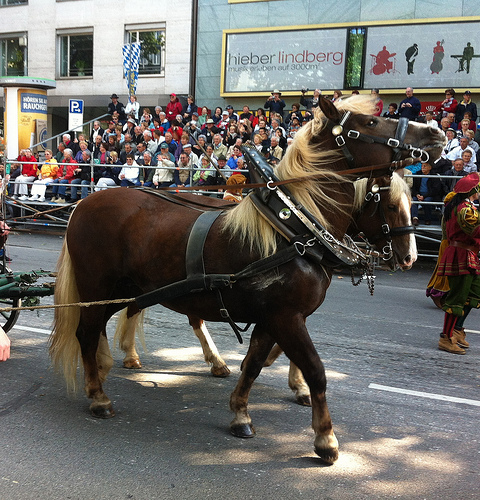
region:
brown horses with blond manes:
[44, 80, 452, 483]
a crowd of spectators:
[13, 64, 314, 178]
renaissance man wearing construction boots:
[432, 168, 477, 362]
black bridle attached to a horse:
[40, 83, 433, 318]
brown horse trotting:
[35, 62, 444, 470]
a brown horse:
[41, 81, 449, 463]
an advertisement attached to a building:
[211, 17, 475, 97]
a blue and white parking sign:
[51, 83, 86, 133]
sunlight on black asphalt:
[344, 395, 475, 491]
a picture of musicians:
[363, 33, 476, 79]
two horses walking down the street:
[44, 97, 423, 473]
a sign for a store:
[212, 18, 478, 101]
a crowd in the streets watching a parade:
[7, 89, 474, 216]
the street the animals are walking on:
[7, 231, 476, 499]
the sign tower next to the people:
[2, 74, 56, 156]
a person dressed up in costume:
[430, 174, 478, 348]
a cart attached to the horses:
[1, 217, 57, 340]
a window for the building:
[60, 26, 94, 80]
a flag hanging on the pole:
[123, 45, 141, 80]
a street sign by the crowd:
[70, 98, 81, 127]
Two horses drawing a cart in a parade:
[12, 59, 450, 485]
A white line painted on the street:
[365, 364, 474, 423]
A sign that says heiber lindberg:
[225, 35, 360, 91]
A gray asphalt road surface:
[30, 417, 230, 482]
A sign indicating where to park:
[61, 79, 97, 136]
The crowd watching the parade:
[107, 91, 253, 186]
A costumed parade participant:
[424, 145, 478, 359]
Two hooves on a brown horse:
[214, 408, 379, 482]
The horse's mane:
[206, 84, 383, 258]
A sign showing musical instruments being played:
[369, 20, 478, 94]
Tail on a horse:
[44, 211, 100, 386]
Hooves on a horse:
[230, 368, 369, 477]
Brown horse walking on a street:
[60, 180, 368, 471]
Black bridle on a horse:
[205, 138, 359, 268]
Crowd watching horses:
[115, 95, 272, 239]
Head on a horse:
[306, 102, 455, 184]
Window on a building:
[215, 16, 433, 105]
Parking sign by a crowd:
[60, 94, 98, 144]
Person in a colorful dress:
[438, 171, 478, 360]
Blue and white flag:
[116, 28, 175, 91]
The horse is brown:
[88, 197, 342, 373]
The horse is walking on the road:
[49, 336, 418, 475]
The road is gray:
[355, 315, 419, 456]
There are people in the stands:
[42, 75, 399, 194]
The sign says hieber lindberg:
[201, 31, 358, 89]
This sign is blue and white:
[56, 99, 97, 129]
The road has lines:
[339, 354, 476, 447]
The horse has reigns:
[289, 88, 452, 243]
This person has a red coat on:
[12, 150, 49, 189]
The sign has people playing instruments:
[361, 23, 478, 83]